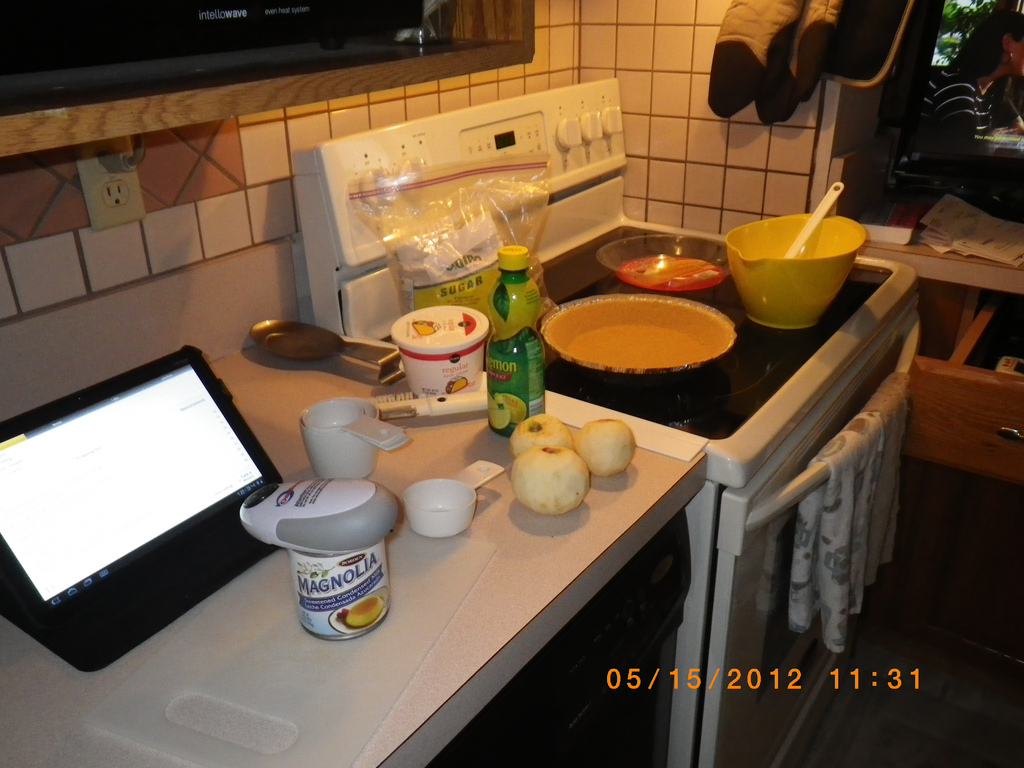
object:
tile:
[726, 123, 772, 170]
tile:
[239, 121, 289, 187]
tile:
[649, 116, 688, 161]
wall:
[2, 0, 815, 315]